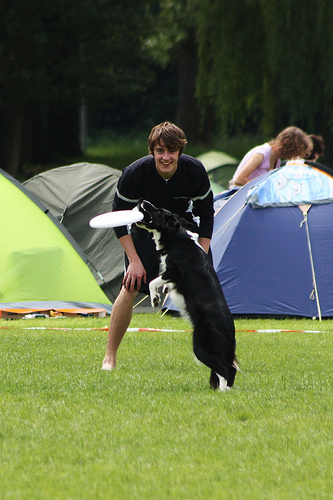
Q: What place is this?
A: It is a field.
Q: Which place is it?
A: It is a field.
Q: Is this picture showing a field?
A: Yes, it is showing a field.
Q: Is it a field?
A: Yes, it is a field.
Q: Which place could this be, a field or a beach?
A: It is a field.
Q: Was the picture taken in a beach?
A: No, the picture was taken in a field.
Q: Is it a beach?
A: No, it is a field.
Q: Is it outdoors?
A: Yes, it is outdoors.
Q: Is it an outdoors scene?
A: Yes, it is outdoors.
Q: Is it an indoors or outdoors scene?
A: It is outdoors.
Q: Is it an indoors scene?
A: No, it is outdoors.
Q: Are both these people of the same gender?
A: No, they are both male and female.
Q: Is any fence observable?
A: No, there are no fences.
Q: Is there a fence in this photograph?
A: No, there are no fences.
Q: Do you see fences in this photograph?
A: No, there are no fences.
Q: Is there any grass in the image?
A: Yes, there is grass.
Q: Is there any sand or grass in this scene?
A: Yes, there is grass.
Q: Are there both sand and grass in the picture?
A: No, there is grass but no sand.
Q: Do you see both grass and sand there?
A: No, there is grass but no sand.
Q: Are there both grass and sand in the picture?
A: No, there is grass but no sand.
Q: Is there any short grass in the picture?
A: Yes, there is short grass.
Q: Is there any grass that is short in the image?
A: Yes, there is short grass.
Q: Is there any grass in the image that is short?
A: Yes, there is grass that is short.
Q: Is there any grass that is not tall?
A: Yes, there is short grass.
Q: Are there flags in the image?
A: No, there are no flags.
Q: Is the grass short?
A: Yes, the grass is short.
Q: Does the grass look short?
A: Yes, the grass is short.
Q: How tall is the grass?
A: The grass is short.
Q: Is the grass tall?
A: No, the grass is short.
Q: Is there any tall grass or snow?
A: No, there is grass but it is short.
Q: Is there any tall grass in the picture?
A: No, there is grass but it is short.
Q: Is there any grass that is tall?
A: No, there is grass but it is short.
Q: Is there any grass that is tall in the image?
A: No, there is grass but it is short.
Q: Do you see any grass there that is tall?
A: No, there is grass but it is short.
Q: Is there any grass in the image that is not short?
A: No, there is grass but it is short.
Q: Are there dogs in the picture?
A: Yes, there is a dog.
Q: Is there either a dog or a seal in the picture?
A: Yes, there is a dog.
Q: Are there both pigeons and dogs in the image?
A: No, there is a dog but no pigeons.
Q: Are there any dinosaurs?
A: No, there are no dinosaurs.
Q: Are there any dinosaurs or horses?
A: No, there are no dinosaurs or horses.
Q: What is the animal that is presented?
A: The animal is a dog.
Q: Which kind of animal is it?
A: The animal is a dog.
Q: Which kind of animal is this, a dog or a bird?
A: That is a dog.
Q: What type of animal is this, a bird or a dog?
A: That is a dog.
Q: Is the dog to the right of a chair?
A: No, the dog is to the right of the tent.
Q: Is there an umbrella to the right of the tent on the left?
A: No, there is a dog to the right of the tent.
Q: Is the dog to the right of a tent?
A: Yes, the dog is to the right of a tent.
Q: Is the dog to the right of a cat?
A: No, the dog is to the right of a tent.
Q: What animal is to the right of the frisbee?
A: The animal is a dog.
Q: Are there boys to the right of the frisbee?
A: No, there is a dog to the right of the frisbee.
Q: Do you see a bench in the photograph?
A: No, there are no benches.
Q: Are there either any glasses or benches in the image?
A: No, there are no benches or glasses.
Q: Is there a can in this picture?
A: No, there are no cans.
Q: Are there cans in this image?
A: No, there are no cans.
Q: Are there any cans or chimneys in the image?
A: No, there are no cans or chimneys.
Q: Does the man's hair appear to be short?
A: Yes, the hair is short.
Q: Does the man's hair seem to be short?
A: Yes, the hair is short.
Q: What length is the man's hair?
A: The hair is short.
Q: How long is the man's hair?
A: The hair is short.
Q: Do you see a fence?
A: No, there are no fences.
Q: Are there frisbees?
A: Yes, there is a frisbee.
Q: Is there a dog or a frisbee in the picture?
A: Yes, there is a frisbee.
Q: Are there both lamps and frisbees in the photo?
A: No, there is a frisbee but no lamps.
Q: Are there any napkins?
A: No, there are no napkins.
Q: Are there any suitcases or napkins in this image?
A: No, there are no napkins or suitcases.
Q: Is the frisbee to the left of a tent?
A: Yes, the frisbee is to the left of a tent.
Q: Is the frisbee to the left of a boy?
A: No, the frisbee is to the left of a tent.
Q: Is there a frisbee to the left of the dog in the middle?
A: Yes, there is a frisbee to the left of the dog.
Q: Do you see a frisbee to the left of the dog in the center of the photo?
A: Yes, there is a frisbee to the left of the dog.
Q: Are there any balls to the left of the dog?
A: No, there is a frisbee to the left of the dog.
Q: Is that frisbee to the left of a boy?
A: No, the frisbee is to the left of the dog.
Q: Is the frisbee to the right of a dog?
A: No, the frisbee is to the left of a dog.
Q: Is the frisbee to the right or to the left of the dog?
A: The frisbee is to the left of the dog.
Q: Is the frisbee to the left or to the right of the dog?
A: The frisbee is to the left of the dog.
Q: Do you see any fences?
A: No, there are no fences.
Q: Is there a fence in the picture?
A: No, there are no fences.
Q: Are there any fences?
A: No, there are no fences.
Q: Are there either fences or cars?
A: No, there are no fences or cars.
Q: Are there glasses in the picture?
A: No, there are no glasses.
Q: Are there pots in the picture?
A: No, there are no pots.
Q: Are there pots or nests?
A: No, there are no pots or nests.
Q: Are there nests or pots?
A: No, there are no pots or nests.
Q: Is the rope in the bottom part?
A: Yes, the rope is in the bottom of the image.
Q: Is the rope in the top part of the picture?
A: No, the rope is in the bottom of the image.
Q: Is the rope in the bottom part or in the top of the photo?
A: The rope is in the bottom of the image.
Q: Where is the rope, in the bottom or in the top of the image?
A: The rope is in the bottom of the image.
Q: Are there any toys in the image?
A: No, there are no toys.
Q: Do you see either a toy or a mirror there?
A: No, there are no toys or mirrors.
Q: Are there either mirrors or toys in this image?
A: No, there are no toys or mirrors.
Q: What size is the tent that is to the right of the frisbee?
A: The tent is little.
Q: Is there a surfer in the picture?
A: No, there are no surfers.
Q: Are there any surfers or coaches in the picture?
A: No, there are no surfers or coaches.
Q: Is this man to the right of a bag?
A: No, the man is to the right of the tent.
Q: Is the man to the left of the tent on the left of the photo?
A: No, the man is to the right of the tent.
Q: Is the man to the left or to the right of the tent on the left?
A: The man is to the right of the tent.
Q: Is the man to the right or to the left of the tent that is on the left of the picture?
A: The man is to the right of the tent.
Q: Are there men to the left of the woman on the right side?
A: Yes, there is a man to the left of the woman.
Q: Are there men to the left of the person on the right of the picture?
A: Yes, there is a man to the left of the woman.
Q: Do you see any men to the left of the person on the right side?
A: Yes, there is a man to the left of the woman.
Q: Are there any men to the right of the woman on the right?
A: No, the man is to the left of the woman.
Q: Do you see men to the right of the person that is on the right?
A: No, the man is to the left of the woman.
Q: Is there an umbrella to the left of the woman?
A: No, there is a man to the left of the woman.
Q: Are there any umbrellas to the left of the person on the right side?
A: No, there is a man to the left of the woman.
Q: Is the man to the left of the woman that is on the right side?
A: Yes, the man is to the left of the woman.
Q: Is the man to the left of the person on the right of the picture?
A: Yes, the man is to the left of the woman.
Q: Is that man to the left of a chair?
A: No, the man is to the left of the woman.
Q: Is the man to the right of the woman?
A: No, the man is to the left of the woman.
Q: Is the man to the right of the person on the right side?
A: No, the man is to the left of the woman.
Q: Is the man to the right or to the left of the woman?
A: The man is to the left of the woman.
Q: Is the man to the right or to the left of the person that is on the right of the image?
A: The man is to the left of the woman.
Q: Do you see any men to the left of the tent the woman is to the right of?
A: Yes, there is a man to the left of the tent.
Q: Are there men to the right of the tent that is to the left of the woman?
A: No, the man is to the left of the tent.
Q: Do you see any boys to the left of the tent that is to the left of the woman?
A: No, there is a man to the left of the tent.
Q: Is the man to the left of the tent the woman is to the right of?
A: Yes, the man is to the left of the tent.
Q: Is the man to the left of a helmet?
A: No, the man is to the left of the tent.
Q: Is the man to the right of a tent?
A: No, the man is to the left of a tent.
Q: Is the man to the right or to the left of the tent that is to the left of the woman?
A: The man is to the left of the tent.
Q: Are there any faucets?
A: No, there are no faucets.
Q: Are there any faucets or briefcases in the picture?
A: No, there are no faucets or briefcases.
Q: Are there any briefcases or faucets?
A: No, there are no faucets or briefcases.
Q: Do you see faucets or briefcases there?
A: No, there are no faucets or briefcases.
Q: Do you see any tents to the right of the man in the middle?
A: Yes, there is a tent to the right of the man.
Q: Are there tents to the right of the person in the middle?
A: Yes, there is a tent to the right of the man.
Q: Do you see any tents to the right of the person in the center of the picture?
A: Yes, there is a tent to the right of the man.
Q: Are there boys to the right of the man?
A: No, there is a tent to the right of the man.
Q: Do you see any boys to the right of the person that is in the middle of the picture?
A: No, there is a tent to the right of the man.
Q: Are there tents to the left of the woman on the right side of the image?
A: Yes, there is a tent to the left of the woman.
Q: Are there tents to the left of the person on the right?
A: Yes, there is a tent to the left of the woman.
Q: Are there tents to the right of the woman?
A: No, the tent is to the left of the woman.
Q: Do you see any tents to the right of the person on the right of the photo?
A: No, the tent is to the left of the woman.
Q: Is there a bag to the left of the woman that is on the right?
A: No, there is a tent to the left of the woman.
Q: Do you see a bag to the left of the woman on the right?
A: No, there is a tent to the left of the woman.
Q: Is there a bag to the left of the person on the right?
A: No, there is a tent to the left of the woman.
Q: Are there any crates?
A: No, there are no crates.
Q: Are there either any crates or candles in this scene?
A: No, there are no crates or candles.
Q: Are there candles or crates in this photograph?
A: No, there are no crates or candles.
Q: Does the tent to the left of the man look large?
A: No, the tent is little.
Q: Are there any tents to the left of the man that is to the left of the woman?
A: Yes, there is a tent to the left of the man.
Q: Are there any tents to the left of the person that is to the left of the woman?
A: Yes, there is a tent to the left of the man.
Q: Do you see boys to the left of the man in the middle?
A: No, there is a tent to the left of the man.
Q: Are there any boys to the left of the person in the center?
A: No, there is a tent to the left of the man.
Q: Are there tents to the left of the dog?
A: Yes, there is a tent to the left of the dog.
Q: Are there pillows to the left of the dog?
A: No, there is a tent to the left of the dog.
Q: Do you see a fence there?
A: No, there are no fences.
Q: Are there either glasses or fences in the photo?
A: No, there are no fences or glasses.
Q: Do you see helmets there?
A: No, there are no helmets.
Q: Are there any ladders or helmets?
A: No, there are no helmets or ladders.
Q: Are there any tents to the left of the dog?
A: Yes, there is a tent to the left of the dog.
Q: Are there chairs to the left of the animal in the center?
A: No, there is a tent to the left of the dog.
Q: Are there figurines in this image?
A: No, there are no figurines.